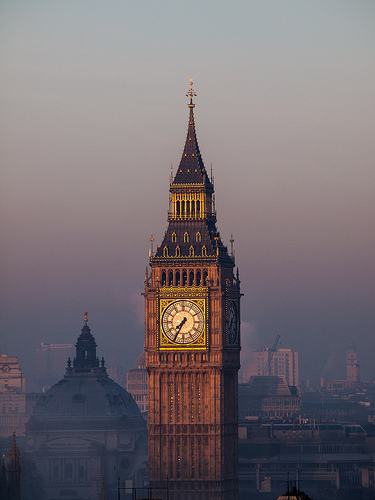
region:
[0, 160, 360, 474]
picture is taken at dusk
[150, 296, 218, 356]
building has a clock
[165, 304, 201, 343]
roman numerals on the face of clock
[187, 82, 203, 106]
object on top of building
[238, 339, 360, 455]
landscape of the city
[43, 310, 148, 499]
building next to clock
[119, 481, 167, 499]
gate on side of clock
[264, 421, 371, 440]
bridge in background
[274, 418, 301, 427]
people standing on the bridge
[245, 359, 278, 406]
shadow from the sun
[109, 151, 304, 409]
The tower has a clock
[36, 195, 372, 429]
The sky is gray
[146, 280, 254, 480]
The tower is brown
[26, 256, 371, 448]
The photo was taken during the day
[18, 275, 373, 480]
There are buildings all around the towers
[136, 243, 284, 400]
The clock reads 7:35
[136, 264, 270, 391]
The brown tower has a clock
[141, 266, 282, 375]
There are two clocks shown in the picture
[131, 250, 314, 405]
There are two clocks shown on the brown tower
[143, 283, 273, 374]
Both clocks read 7:35pm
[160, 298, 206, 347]
The clock face square to the camera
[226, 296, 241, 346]
The clock face that is narrowed because of the angle of photo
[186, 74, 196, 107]
The top piece of the focus building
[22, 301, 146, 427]
The dome of the building to the left of the clock tower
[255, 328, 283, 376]
The crane visible in background to the right of clock tower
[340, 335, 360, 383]
The tall building near the right edge with a green dome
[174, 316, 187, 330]
The hour hand of the main clock face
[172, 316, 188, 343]
The minute hand of the main clock face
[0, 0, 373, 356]
The hazy or smoggy sky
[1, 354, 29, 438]
The building on the left edge with a circle that may be a clock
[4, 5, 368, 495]
Exterior view, dusky sky, suggesting overcast morning, or summer evening.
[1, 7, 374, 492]
View of historical architecture and city skyline.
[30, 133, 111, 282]
Purple, overcast-looking sky, suggesting early morn, or evening.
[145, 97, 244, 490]
Ornate tower, with steeple and clock face.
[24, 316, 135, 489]
Shadowy, domed building, suggestive of church.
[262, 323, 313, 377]
High-rise, buildings in distance, right, with crane.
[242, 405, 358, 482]
Train, on bridge, in urban area.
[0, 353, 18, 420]
Tall building, with clock, in left, distance.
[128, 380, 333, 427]
Large buildings, beyond tower.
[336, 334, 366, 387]
Large building, enveloped in fog.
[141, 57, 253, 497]
tall tower with a clock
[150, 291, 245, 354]
you can see a clock on two sides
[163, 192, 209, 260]
the tower has gold accents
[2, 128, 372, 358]
the city looks to be very hazy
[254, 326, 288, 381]
a tall crane in the distance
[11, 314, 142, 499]
a wide rounded building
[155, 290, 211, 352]
the clock has gold accents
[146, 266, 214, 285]
a row of windows above the clock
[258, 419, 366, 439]
a low lying buildling with a flat roof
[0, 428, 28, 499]
a very thin tower shaped structure to the left